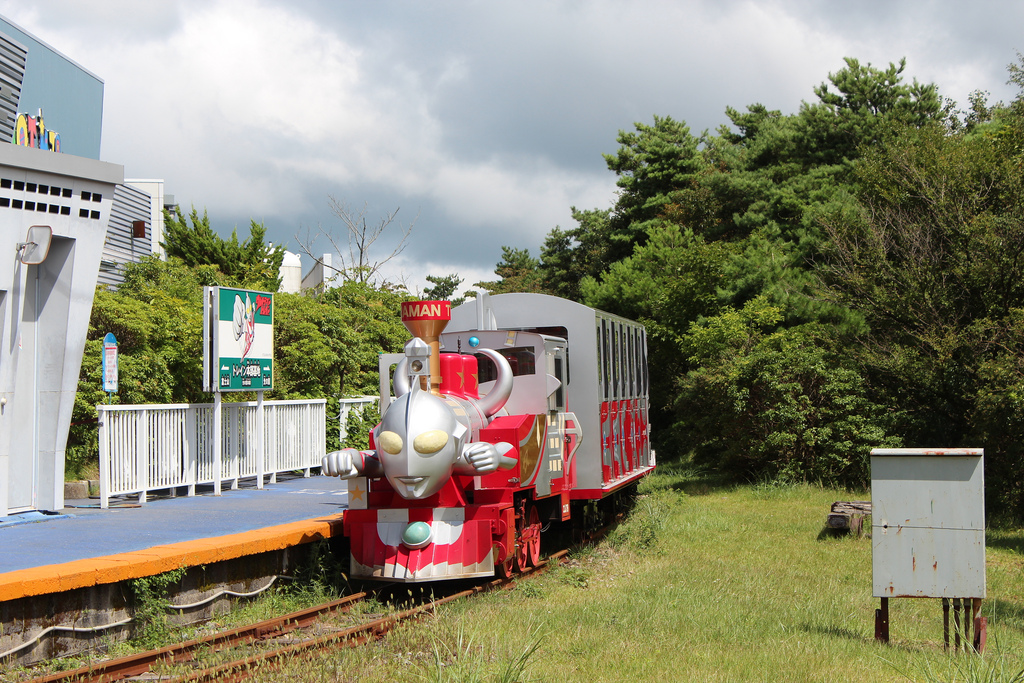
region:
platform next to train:
[0, 442, 361, 605]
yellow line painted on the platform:
[4, 503, 336, 602]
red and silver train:
[378, 272, 679, 590]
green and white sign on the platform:
[206, 279, 280, 396]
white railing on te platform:
[88, 403, 329, 499]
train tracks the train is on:
[83, 561, 535, 679]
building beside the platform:
[10, 17, 118, 512]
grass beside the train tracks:
[288, 449, 1009, 677]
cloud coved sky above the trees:
[28, 4, 1008, 299]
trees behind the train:
[64, 47, 1020, 458]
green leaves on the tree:
[686, 313, 729, 339]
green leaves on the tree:
[702, 356, 763, 430]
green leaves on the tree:
[866, 322, 940, 408]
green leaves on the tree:
[871, 277, 979, 408]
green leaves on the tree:
[843, 114, 901, 207]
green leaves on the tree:
[707, 225, 790, 299]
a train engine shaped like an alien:
[344, 287, 566, 588]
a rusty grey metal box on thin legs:
[853, 427, 1019, 662]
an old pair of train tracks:
[145, 594, 420, 678]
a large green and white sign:
[196, 272, 285, 409]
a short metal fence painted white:
[70, 375, 342, 494]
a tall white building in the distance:
[242, 233, 348, 298]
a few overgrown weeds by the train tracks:
[224, 584, 453, 668]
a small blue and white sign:
[98, 313, 128, 408]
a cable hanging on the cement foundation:
[15, 565, 317, 632]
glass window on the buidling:
[8, 178, 25, 189]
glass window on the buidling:
[32, 182, 49, 193]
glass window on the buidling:
[45, 185, 58, 190]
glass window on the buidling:
[54, 185, 74, 196]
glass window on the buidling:
[73, 185, 93, 199]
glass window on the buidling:
[74, 198, 91, 217]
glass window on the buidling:
[84, 201, 97, 218]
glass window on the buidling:
[57, 200, 73, 219]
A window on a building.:
[78, 206, 92, 219]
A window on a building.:
[97, 196, 104, 204]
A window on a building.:
[91, 209, 101, 220]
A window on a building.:
[75, 209, 91, 217]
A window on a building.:
[60, 185, 71, 196]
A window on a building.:
[62, 201, 72, 214]